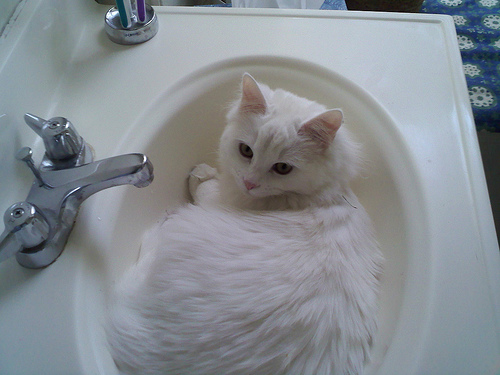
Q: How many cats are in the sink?
A: 1.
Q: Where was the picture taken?
A: Bathroom.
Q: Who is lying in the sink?
A: The cat.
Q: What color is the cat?
A: White.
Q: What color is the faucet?
A: Silver.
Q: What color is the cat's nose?
A: Pink.